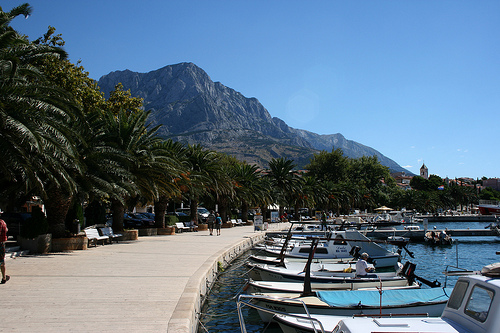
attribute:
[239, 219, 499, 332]
row — of boats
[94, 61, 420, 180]
moutain — background, rocky, large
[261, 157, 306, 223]
tree — background, palm, in row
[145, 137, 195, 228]
tree — background, palm, in row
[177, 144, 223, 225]
tree — background, palm, in row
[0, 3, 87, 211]
tree — background, palm, in row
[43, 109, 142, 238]
tree — background, palm, in row, small palm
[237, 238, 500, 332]
boat — docked, white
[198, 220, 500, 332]
water — blue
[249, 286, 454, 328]
boat — docked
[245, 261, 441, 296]
boat — docked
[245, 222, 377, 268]
boat — docked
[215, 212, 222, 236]
person — background, walking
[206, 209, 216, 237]
person — background, walking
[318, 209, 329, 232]
person — background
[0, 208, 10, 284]
person — background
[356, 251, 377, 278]
person — background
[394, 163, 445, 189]
building — background, distant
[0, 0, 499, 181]
sky — clear, bright blue, clear blue daytime, light blue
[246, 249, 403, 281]
boat — docked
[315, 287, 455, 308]
cover — blue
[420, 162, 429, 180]
steeple — distant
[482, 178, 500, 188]
building — background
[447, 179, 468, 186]
building — background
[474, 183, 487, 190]
building — background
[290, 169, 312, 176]
building — background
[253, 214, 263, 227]
sign — white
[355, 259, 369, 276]
shirt — white